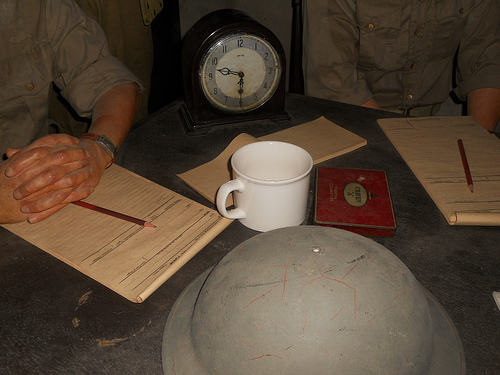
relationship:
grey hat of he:
[161, 221, 465, 373] [0, 0, 145, 227]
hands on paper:
[4, 116, 114, 228] [11, 164, 256, 317]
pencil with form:
[73, 197, 157, 231] [3, 137, 236, 304]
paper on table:
[288, 100, 378, 175] [413, 218, 498, 305]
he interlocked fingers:
[0, 0, 145, 227] [4, 139, 103, 224]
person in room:
[299, 0, 499, 127] [3, 4, 498, 371]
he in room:
[0, 0, 145, 227] [3, 4, 498, 371]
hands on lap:
[380, 110, 497, 144] [373, 104, 494, 135]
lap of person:
[373, 104, 494, 135] [296, 21, 498, 151]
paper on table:
[358, 99, 498, 256] [2, 63, 499, 370]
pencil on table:
[451, 135, 477, 196] [2, 63, 499, 370]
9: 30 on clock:
[206, 62, 254, 110] [155, 7, 331, 126]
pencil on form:
[70, 200, 157, 227] [0, 163, 236, 304]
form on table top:
[0, 163, 236, 304] [1, 106, 498, 374]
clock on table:
[177, 6, 294, 126] [2, 63, 499, 370]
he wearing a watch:
[6, 7, 132, 226] [90, 127, 121, 163]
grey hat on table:
[161, 224, 466, 375] [2, 63, 499, 370]